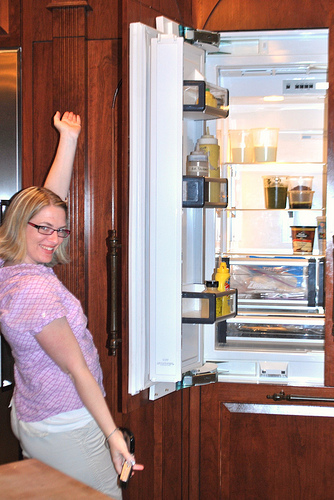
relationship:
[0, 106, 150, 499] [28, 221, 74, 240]
woman wearing glasses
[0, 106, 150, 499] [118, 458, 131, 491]
woman holding item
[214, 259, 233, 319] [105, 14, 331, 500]
mustard in refrigerator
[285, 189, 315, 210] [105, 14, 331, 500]
salsa inside refrigerator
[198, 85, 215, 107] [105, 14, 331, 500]
lemon juice inside refrigerator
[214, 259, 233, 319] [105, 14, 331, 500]
mustard inside refrigerator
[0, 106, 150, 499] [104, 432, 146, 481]
woman has right hand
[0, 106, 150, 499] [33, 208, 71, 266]
woman has face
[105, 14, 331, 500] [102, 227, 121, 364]
refrigerator has handle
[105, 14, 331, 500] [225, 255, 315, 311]
refrigerator has drawer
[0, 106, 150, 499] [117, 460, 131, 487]
woman holding item